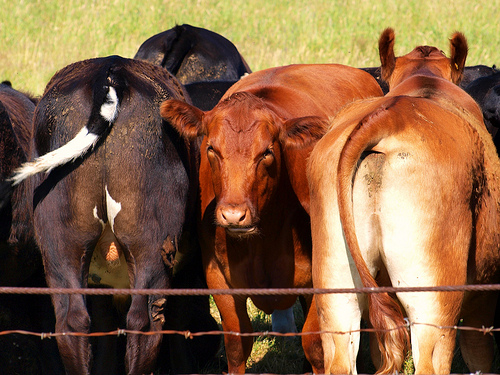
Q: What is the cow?
A: Brown.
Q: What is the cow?
A: Brown.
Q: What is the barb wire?
A: Rusty.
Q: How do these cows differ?
A: In color.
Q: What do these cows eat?
A: The grass.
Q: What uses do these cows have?
A: Meat and dairy.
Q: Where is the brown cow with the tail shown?
A: On the right.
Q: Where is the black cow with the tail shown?
A: On the left.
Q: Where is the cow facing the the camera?
A: In the middle.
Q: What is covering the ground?
A: Grass.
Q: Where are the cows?
A: Grass field.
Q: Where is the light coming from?
A: Sun.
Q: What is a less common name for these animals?
A: Bovine.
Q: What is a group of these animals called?
A: Herd.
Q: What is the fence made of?
A: Metal.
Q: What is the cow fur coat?
A: Light brown.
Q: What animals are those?
A: Cows.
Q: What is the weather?
A: Sunny.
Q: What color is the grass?
A: Green.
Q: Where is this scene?
A: Farm.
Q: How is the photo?
A: Clear.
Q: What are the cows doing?
A: Standing.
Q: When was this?
A: Daytime.